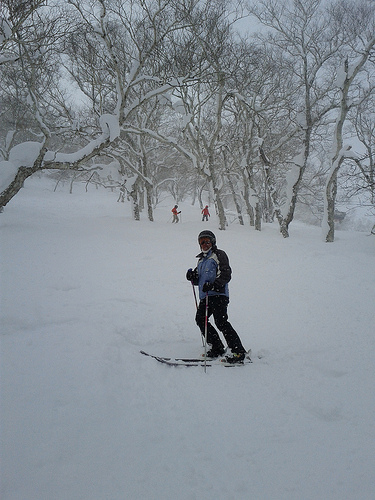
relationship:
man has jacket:
[185, 230, 247, 362] [194, 247, 232, 300]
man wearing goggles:
[185, 230, 247, 362] [197, 237, 212, 244]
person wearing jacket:
[169, 203, 181, 223] [171, 206, 178, 216]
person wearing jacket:
[199, 204, 211, 222] [202, 208, 210, 216]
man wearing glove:
[185, 230, 247, 362] [186, 266, 196, 285]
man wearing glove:
[185, 230, 247, 362] [210, 279, 226, 294]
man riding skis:
[185, 230, 247, 362] [140, 346, 240, 371]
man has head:
[185, 230, 247, 362] [197, 230, 216, 257]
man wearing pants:
[185, 230, 247, 362] [194, 295, 245, 355]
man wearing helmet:
[185, 230, 247, 362] [197, 229, 215, 242]